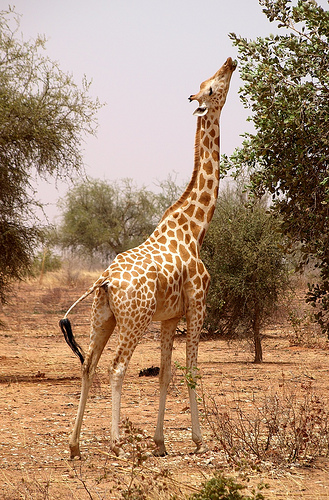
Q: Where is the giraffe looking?
A: Up.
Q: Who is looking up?
A: Giraffe.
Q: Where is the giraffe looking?
A: Up.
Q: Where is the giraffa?
A: Grass.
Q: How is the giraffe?
A: Standing.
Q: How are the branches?
A: Bare.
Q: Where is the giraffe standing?
A: In the dirt.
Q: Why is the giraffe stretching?
A: To eat.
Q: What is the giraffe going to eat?
A: Leaves.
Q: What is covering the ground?
A: Dirt.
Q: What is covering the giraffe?
A: Spots of brown.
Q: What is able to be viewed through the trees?
A: The sky.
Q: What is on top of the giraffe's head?
A: Two horns.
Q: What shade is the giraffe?
A: Brown and white.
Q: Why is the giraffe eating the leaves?
A: I'ts hungry.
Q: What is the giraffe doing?
A: Eating leaves.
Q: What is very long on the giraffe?
A: The neck.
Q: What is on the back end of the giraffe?
A: A tail.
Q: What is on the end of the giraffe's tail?
A: Long hair.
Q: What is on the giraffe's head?
A: Horns.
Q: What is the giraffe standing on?
A: Dirt.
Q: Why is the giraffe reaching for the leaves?
A: To eat them.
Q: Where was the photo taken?
A: Africa.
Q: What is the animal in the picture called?
A: A giraffe.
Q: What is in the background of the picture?
A: Trees.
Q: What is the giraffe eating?
A: Leaves.